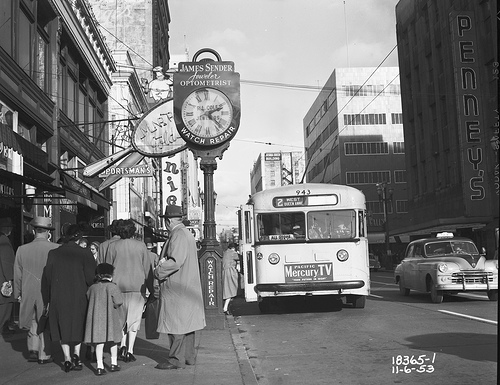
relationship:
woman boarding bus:
[220, 242, 242, 315] [237, 183, 371, 313]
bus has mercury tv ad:
[237, 183, 371, 313] [283, 261, 334, 284]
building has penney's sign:
[384, 1, 500, 262] [447, 9, 492, 216]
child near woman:
[85, 263, 122, 375] [41, 223, 98, 373]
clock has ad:
[173, 48, 241, 329] [177, 64, 234, 88]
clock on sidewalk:
[173, 48, 241, 329] [195, 311, 254, 384]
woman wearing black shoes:
[41, 223, 98, 373] [63, 354, 81, 371]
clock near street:
[173, 48, 241, 329] [231, 270, 499, 385]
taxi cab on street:
[394, 232, 499, 303] [231, 270, 499, 385]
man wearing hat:
[153, 205, 206, 369] [160, 204, 186, 219]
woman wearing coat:
[41, 223, 98, 373] [43, 241, 97, 342]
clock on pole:
[173, 48, 241, 329] [198, 157, 224, 333]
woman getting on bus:
[220, 242, 242, 315] [237, 183, 371, 313]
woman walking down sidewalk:
[41, 223, 98, 373] [195, 311, 254, 384]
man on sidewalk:
[153, 205, 206, 369] [195, 311, 254, 384]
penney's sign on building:
[447, 9, 492, 216] [384, 1, 500, 262]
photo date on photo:
[392, 366, 435, 374] [0, 1, 493, 381]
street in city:
[231, 270, 499, 385] [1, 1, 498, 385]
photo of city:
[0, 1, 493, 381] [1, 1, 498, 385]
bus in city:
[237, 183, 371, 313] [1, 1, 498, 385]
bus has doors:
[237, 183, 371, 313] [239, 203, 256, 300]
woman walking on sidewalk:
[108, 219, 151, 361] [195, 311, 254, 384]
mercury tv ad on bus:
[283, 261, 334, 284] [237, 183, 371, 313]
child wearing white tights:
[85, 263, 122, 375] [96, 343, 104, 369]